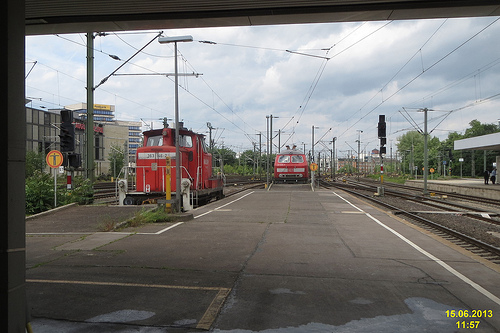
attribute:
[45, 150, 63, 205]
sign — red, yellow, black